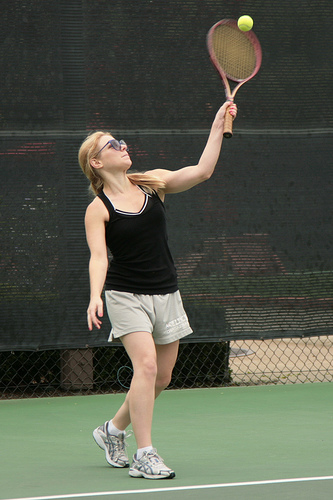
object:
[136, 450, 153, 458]
sock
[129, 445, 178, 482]
foot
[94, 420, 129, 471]
shoe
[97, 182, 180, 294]
top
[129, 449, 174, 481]
shoe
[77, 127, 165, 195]
hair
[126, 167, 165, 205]
shoulder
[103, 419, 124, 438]
bike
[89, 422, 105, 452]
heel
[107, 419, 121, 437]
sock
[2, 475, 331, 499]
line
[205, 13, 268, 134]
racket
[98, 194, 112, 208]
strap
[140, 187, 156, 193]
strap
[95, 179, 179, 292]
shirt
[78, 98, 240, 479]
girl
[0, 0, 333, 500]
court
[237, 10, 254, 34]
ball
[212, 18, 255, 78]
contact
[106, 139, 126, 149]
glasses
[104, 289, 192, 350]
shorts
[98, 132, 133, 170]
face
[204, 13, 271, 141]
living tennis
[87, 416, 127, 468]
feet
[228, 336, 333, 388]
pavement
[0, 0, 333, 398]
fence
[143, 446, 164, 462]
shoe lace